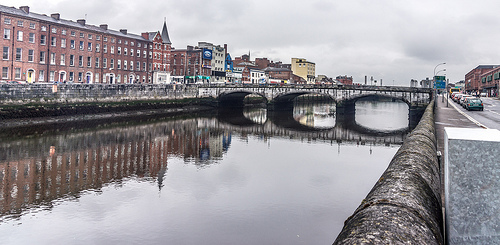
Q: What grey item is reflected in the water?
A: Bridge.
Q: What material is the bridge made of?
A: Stone.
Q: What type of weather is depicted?
A: Cloudy.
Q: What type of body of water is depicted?
A: River.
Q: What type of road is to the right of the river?
A: Paved.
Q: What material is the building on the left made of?
A: Brick.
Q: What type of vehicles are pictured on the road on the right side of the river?
A: Cars.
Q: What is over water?
A: Long bridge.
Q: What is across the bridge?
A: Long building with many windows.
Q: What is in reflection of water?
A: Brick building.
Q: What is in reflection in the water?
A: Long bridge.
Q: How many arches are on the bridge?
A: Three.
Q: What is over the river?
A: Bridge.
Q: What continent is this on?
A: Europe.